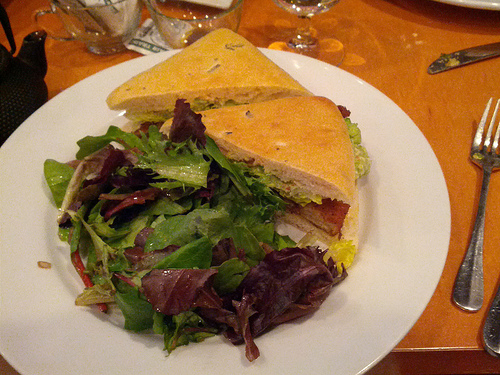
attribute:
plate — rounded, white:
[360, 124, 435, 287]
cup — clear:
[33, 0, 139, 53]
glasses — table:
[38, 0, 333, 50]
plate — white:
[51, 34, 407, 336]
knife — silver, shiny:
[429, 39, 497, 79]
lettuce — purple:
[67, 128, 214, 297]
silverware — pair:
[451, 59, 498, 317]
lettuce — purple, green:
[144, 145, 209, 189]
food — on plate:
[25, 32, 439, 357]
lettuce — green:
[200, 142, 250, 197]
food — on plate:
[68, 74, 327, 309]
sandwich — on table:
[154, 94, 369, 244]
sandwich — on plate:
[132, 44, 304, 109]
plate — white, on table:
[4, 47, 449, 368]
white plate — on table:
[3, 37, 462, 373]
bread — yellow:
[145, 30, 262, 106]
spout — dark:
[0, 31, 87, 116]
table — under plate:
[2, 0, 499, 353]